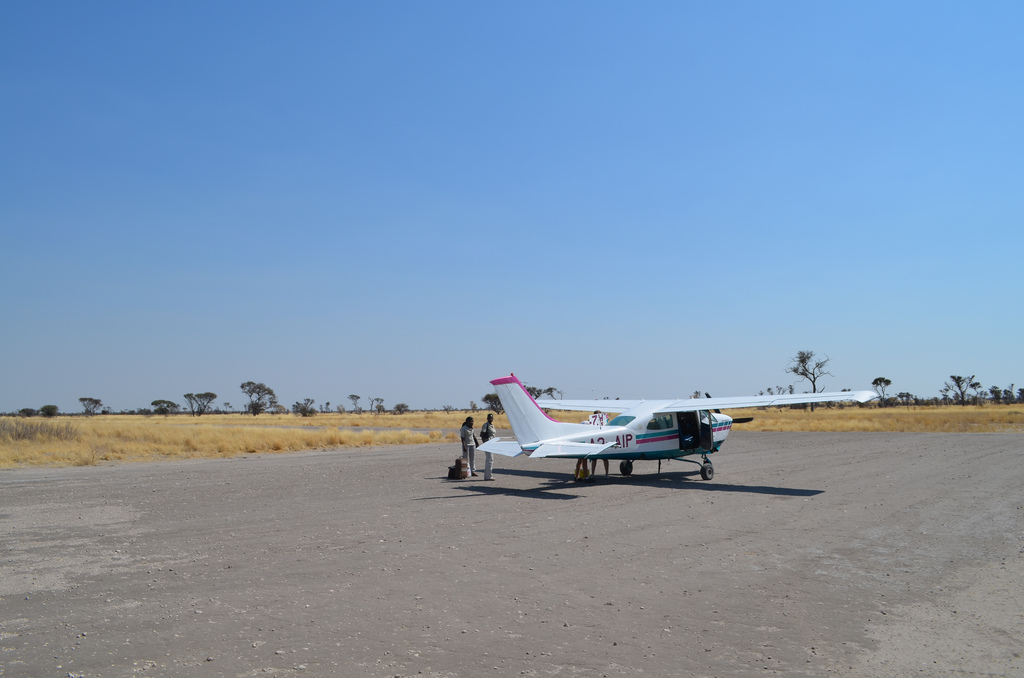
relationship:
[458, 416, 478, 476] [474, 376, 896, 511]
person standing near plane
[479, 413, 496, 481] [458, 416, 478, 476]
people standing near person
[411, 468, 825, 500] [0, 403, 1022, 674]
shadow on ground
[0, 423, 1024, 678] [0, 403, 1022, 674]
grey on ground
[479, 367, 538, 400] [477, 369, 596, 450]
color on wing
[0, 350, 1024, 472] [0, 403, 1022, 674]
distance on ground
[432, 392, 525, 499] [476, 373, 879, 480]
people standing by airplane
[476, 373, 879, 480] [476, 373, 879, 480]
airplane on airplane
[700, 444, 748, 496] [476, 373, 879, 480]
wheel on airplane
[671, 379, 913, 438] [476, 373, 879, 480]
wing on airplane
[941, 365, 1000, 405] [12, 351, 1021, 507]
tree in field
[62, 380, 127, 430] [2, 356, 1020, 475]
tree in field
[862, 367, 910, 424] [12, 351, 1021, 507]
tree in field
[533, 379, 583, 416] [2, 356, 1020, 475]
tree in field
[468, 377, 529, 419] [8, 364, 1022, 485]
tree in field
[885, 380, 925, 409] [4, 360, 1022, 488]
tree in distance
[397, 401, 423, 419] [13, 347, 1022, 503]
tree in distance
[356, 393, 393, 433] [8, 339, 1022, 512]
tree in distance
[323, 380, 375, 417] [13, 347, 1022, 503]
tree in distance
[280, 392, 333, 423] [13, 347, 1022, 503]
tree in distance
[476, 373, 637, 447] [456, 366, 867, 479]
fin of airplane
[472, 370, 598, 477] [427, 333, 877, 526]
fin on a plane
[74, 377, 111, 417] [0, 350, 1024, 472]
tree in a distance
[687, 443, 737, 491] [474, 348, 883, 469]
wheel attached to plane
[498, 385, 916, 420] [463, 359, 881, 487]
wings are attached to plane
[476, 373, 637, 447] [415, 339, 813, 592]
fin of plane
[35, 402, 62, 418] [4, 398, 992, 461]
tree standing in field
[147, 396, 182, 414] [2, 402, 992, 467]
tree standing in field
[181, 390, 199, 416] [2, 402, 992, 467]
tree standing in field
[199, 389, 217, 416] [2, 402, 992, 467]
tree standing in field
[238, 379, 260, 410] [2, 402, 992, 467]
tree standing in field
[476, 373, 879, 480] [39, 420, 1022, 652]
airplane on top of runway